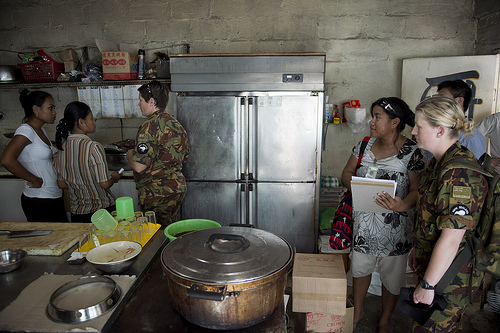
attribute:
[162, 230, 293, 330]
pot — filthy, huge, large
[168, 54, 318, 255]
fridge — metal, industrial, stainless steel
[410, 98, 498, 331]
soldier — watching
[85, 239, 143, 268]
dishes — dirty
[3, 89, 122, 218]
girls — cooking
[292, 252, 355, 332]
boxes — cardboard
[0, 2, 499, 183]
cement wall — dirty, grey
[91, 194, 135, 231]
containers — green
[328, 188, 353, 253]
purse — red, black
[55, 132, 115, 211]
shirt — striped